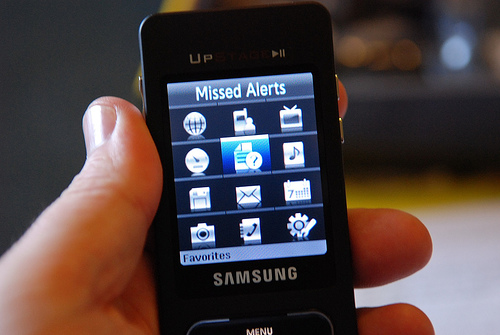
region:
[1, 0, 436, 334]
Hand holding a black cellphone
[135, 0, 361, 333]
Black Samsung cellphone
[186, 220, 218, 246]
Silver camera menu icon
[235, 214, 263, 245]
Silver telephone book contacts menu icon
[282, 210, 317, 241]
Silver tools and settings menu icon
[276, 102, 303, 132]
Silver television menu icon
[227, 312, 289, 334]
Menu button on a cellphone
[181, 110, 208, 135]
Silver internet icon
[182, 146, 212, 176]
Silver clock menu icon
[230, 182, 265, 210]
Silver envelope menu icon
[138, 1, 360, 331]
black samsung cell phone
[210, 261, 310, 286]
samsung written on phone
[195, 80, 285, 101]
missed alerts notification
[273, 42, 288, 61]
play and pause symbol on phone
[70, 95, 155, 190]
thumb on left hand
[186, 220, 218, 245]
camera feature on phone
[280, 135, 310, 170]
music on the phone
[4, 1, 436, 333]
Man holding smartphone in his hand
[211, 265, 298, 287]
Brand of phone on front of phone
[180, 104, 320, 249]
Apps on screen of the phone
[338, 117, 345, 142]
Button on side of phone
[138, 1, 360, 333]
Black Samsung phone with apps on screen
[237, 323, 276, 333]
Button on bottom of phone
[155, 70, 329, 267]
Small gray screen on phone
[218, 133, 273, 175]
Highlighted icon on phone screen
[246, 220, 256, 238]
Image of phone on phone screen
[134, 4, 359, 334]
a black samsung mobile phone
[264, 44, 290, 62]
play/pause button on a phone screen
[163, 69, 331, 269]
screen on a mobile phone is illuminated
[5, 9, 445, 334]
hand holding a mobile phone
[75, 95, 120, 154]
left thumb nail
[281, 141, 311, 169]
musical note icon on a cell phone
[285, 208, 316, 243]
settings icon on a phone screen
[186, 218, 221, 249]
camera icon on a mobile phone screen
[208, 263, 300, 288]
manufacturers name on a phone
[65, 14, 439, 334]
hand holding a phone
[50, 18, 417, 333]
hand holding a phone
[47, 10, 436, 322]
hand holding a phone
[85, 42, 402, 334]
hand holding a phone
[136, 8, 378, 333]
a black small phone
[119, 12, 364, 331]
a black small phone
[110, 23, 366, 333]
a black small phone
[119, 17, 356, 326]
a black small phone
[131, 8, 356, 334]
a black small phone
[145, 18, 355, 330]
a cellphone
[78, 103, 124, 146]
a thumb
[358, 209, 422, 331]
two fingers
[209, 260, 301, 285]
logo on the phone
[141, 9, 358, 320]
a black phone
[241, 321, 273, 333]
letters on the phone